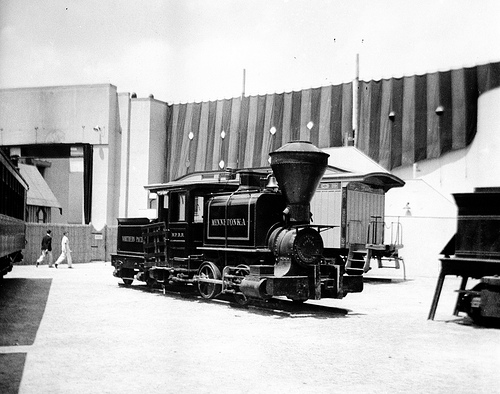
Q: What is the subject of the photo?
A: Trains.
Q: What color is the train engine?
A: Black.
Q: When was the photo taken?
A: Daytime.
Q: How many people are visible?
A: Two.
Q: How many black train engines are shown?
A: One.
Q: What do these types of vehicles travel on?
A: Tracks.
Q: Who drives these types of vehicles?
A: Conductor.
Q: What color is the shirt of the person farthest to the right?
A: White.